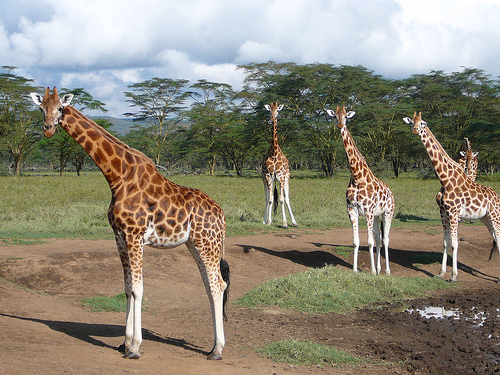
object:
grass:
[246, 263, 351, 309]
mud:
[366, 293, 500, 373]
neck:
[60, 105, 150, 190]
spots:
[267, 157, 290, 176]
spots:
[137, 181, 166, 204]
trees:
[6, 64, 498, 179]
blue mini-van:
[28, 79, 232, 361]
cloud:
[6, 1, 500, 103]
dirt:
[161, 297, 210, 346]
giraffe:
[401, 110, 499, 280]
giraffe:
[262, 102, 299, 229]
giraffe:
[460, 150, 480, 181]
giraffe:
[325, 105, 394, 277]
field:
[1, 167, 496, 373]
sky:
[4, 1, 499, 113]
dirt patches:
[77, 264, 459, 368]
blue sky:
[0, 0, 499, 119]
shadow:
[235, 244, 362, 272]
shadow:
[307, 242, 500, 284]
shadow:
[0, 313, 216, 356]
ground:
[1, 173, 498, 373]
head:
[28, 84, 74, 138]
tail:
[218, 209, 231, 323]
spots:
[152, 208, 183, 231]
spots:
[454, 185, 479, 206]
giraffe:
[30, 86, 231, 360]